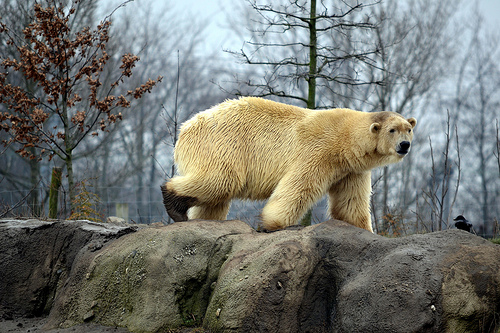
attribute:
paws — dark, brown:
[143, 164, 223, 209]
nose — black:
[394, 139, 416, 154]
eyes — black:
[401, 122, 410, 133]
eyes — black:
[388, 125, 393, 135]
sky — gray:
[393, 21, 461, 59]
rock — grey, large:
[225, 219, 392, 329]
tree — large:
[10, 3, 160, 218]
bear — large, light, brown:
[163, 79, 425, 226]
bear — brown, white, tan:
[158, 96, 413, 231]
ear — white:
[368, 123, 380, 133]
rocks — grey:
[5, 212, 486, 312]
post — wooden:
[46, 164, 66, 220]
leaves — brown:
[12, 8, 127, 177]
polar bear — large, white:
[155, 85, 415, 235]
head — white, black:
[362, 98, 419, 167]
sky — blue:
[1, 1, 498, 230]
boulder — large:
[34, 213, 497, 293]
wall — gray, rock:
[3, 220, 498, 329]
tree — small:
[304, 3, 331, 118]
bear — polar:
[138, 73, 438, 244]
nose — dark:
[399, 142, 416, 151]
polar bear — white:
[140, 82, 430, 250]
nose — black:
[397, 134, 407, 158]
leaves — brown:
[122, 49, 142, 76]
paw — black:
[157, 180, 198, 221]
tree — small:
[14, 8, 87, 218]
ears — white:
[368, 117, 381, 134]